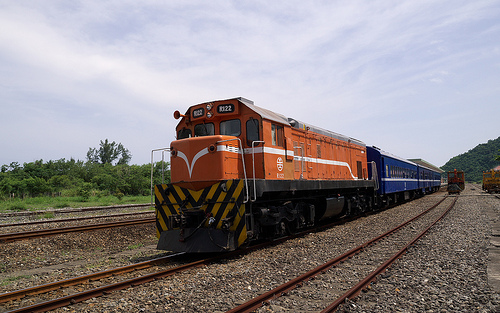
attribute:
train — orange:
[144, 104, 328, 223]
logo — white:
[274, 155, 284, 170]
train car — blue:
[371, 142, 451, 204]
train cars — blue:
[367, 144, 444, 195]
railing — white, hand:
[248, 137, 265, 199]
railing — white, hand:
[216, 136, 248, 203]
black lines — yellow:
[148, 175, 250, 248]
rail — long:
[304, 187, 456, 312]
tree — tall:
[74, 134, 137, 191]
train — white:
[147, 91, 445, 256]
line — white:
[213, 141, 294, 157]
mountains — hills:
[437, 134, 498, 191]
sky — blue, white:
[2, 0, 499, 166]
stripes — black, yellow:
[154, 180, 244, 234]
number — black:
[216, 102, 232, 115]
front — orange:
[149, 97, 264, 254]